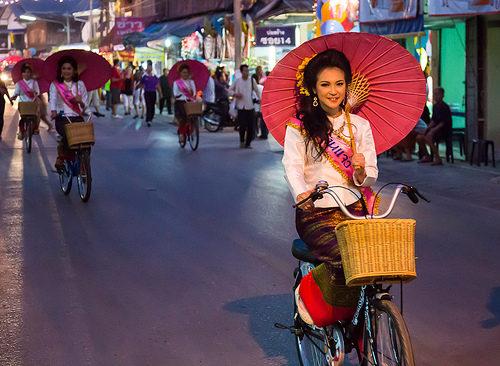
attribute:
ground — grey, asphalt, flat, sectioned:
[119, 189, 235, 283]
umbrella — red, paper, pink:
[381, 61, 431, 110]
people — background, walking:
[17, 50, 230, 148]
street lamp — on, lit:
[11, 4, 43, 28]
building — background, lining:
[103, 13, 275, 57]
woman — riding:
[301, 60, 355, 147]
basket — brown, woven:
[329, 215, 421, 282]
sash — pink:
[318, 134, 352, 164]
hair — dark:
[295, 110, 339, 139]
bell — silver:
[309, 180, 328, 200]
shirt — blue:
[427, 104, 455, 125]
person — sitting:
[425, 85, 457, 151]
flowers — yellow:
[292, 61, 314, 91]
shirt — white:
[290, 106, 380, 194]